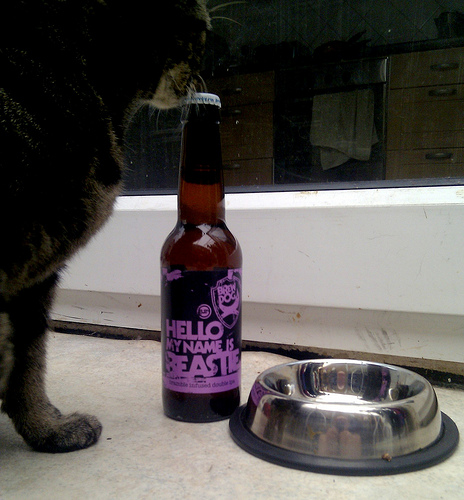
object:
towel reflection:
[309, 94, 380, 171]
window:
[124, 0, 464, 195]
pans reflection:
[309, 27, 370, 49]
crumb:
[383, 453, 393, 462]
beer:
[160, 92, 243, 422]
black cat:
[0, 0, 211, 453]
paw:
[32, 409, 103, 453]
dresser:
[385, 44, 463, 178]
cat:
[1, 4, 216, 455]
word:
[164, 320, 224, 340]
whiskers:
[181, 75, 208, 124]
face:
[156, 1, 210, 110]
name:
[183, 340, 223, 354]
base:
[228, 413, 458, 473]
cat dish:
[229, 357, 461, 478]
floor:
[85, 369, 211, 494]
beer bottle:
[159, 93, 243, 423]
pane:
[101, 0, 464, 194]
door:
[271, 55, 387, 186]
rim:
[256, 458, 441, 476]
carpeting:
[0, 331, 464, 500]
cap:
[182, 91, 223, 109]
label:
[158, 270, 243, 390]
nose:
[191, 87, 199, 92]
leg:
[1, 276, 103, 454]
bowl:
[227, 357, 458, 474]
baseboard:
[58, 185, 463, 316]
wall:
[56, 185, 463, 374]